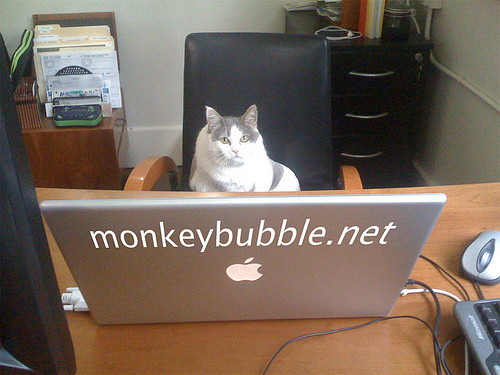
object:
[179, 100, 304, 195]
cat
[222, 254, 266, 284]
logo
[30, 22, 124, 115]
envelopes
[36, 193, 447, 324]
laptop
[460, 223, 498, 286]
mouse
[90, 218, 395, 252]
text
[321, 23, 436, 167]
drawer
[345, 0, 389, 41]
group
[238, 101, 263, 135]
ears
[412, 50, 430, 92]
lock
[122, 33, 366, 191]
chair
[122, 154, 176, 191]
arm rests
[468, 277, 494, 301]
wires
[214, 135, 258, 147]
eyes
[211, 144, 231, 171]
whiskers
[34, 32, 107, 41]
papers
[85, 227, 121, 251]
m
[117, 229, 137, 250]
o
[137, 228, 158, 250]
n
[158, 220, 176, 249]
k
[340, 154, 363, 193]
handles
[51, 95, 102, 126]
device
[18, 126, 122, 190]
cabinet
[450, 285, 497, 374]
keyboard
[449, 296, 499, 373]
edge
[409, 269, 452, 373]
wires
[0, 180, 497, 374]
desk